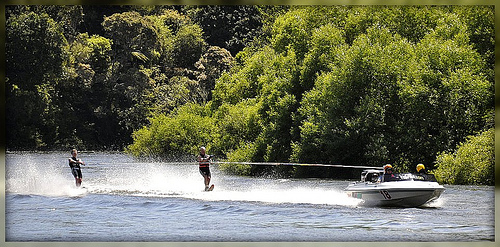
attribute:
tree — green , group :
[96, 7, 209, 146]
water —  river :
[11, 150, 499, 242]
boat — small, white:
[344, 178, 444, 208]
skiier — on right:
[194, 144, 229, 204]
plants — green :
[8, 9, 490, 177]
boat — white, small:
[342, 124, 475, 242]